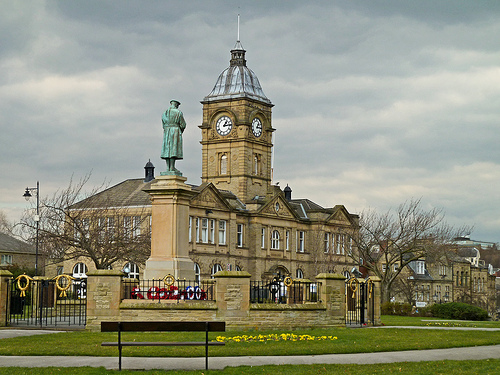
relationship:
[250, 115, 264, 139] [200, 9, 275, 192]
clock on tower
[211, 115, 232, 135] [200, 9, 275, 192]
clock on tower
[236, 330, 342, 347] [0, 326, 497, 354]
yellow flowers in center of grass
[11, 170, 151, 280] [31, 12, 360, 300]
bare tree outside of building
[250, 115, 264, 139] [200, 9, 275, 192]
clock in tower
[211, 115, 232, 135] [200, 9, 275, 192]
clock in tower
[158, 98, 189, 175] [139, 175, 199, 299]
statue on top of tower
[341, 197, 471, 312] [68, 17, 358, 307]
bare tree next to building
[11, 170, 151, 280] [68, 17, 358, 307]
bare tree next to building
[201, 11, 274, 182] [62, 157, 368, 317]
clocktower on top of building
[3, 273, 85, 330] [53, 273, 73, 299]
gate with decoration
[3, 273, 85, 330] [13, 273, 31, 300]
gate with decoration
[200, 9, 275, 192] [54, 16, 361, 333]
tower on top of building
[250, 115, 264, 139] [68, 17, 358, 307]
clock near top of building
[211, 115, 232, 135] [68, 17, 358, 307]
clock near top of building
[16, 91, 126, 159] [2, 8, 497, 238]
sky filled with clouds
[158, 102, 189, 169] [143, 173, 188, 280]
statue on pedestal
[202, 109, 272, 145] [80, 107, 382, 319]
two clocks on side of building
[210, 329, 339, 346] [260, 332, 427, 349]
flowers in grass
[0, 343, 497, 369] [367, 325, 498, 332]
path cutting through path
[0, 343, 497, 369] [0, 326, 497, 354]
path cutting through grass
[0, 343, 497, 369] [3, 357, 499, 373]
path cutting through grass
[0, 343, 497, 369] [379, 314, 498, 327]
path cutting through grass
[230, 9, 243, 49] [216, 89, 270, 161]
pole on top of tower